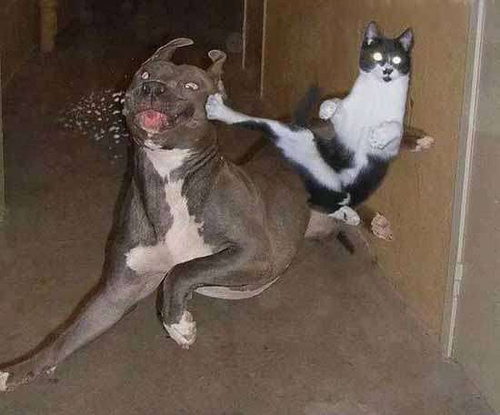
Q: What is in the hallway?
A: Dog and cat.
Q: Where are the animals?
A: Hallway.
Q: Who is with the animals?
A: No one.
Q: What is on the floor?
A: Carpet.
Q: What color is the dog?
A: Brown.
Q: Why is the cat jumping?
A: Playing.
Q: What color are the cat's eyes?
A: Yellow.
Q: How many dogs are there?
A: One.